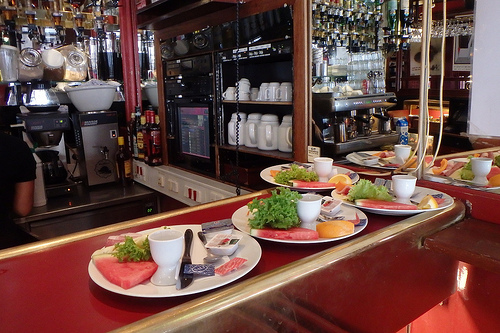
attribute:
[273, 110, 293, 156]
water jug — white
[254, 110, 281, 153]
water jug — white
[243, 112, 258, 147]
water jug — white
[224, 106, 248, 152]
water jug — white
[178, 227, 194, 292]
butter knife — silver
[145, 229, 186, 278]
cupe — white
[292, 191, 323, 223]
cupe — white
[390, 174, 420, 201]
cupe — white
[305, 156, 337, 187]
cupe — white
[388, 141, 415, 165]
cupe — white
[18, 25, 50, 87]
canister — clear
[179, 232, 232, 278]
spoon — silver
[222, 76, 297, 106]
mugs — white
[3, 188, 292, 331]
counter top — red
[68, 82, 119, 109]
big bowl — white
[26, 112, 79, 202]
coffee pot — by the bowl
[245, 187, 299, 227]
green vegetable — on a plate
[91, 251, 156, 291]
sliced watermelon — on a plate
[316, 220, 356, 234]
sliced orange — on a plate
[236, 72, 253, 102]
stack/cups — on a shelf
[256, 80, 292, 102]
coffee cups — white, on a shelf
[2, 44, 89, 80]
glass canisters — clear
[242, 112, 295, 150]
white jugs — on a shelf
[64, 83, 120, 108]
large bowl — white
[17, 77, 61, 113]
coffe pot — with coffee in it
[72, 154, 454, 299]
four plates — of food, on a counter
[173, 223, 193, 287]
silver knife — on table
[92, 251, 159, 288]
watermelon — on plate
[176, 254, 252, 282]
satchets — on plate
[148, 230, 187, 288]
egg holder — on plate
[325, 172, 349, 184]
lemon — on plate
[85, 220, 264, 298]
round plate — white, on counter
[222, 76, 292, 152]
white cups/teapots — on shelf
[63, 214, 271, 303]
plate — white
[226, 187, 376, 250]
plate — white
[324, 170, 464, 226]
plate — white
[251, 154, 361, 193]
plate — white